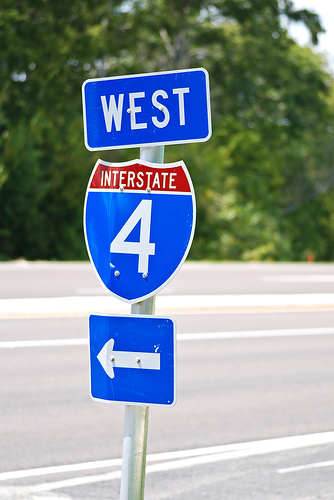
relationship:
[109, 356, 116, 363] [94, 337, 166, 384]
screw holds up arrow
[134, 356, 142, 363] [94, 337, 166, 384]
screw holds up arrow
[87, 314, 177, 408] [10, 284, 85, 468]
left turn points to interstate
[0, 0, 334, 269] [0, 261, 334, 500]
trees lining road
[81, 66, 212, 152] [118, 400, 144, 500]
blue sign on pole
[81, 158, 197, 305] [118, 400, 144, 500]
interstate sign on pole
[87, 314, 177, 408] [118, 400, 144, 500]
left turn on pole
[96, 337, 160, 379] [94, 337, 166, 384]
arrow on arrow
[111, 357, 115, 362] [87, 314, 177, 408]
screw holding left turn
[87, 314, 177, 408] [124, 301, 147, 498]
left turn attached to pole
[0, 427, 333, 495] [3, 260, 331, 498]
lines are on street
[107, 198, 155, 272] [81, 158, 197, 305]
four on interstate sign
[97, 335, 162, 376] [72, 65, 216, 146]
arrow on blue sign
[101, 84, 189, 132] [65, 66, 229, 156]
letter on sign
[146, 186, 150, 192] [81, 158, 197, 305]
screw hold interstate sign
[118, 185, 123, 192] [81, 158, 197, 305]
screw hold interstate sign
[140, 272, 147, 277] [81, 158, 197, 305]
screw hold interstate sign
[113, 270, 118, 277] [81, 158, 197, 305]
screw hold interstate sign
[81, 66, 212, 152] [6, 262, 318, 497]
blue sign on interstate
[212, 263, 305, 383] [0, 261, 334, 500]
interstate with interstate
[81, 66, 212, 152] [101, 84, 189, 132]
blue sign reads letter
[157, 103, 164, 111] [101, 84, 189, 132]
screw hold letter